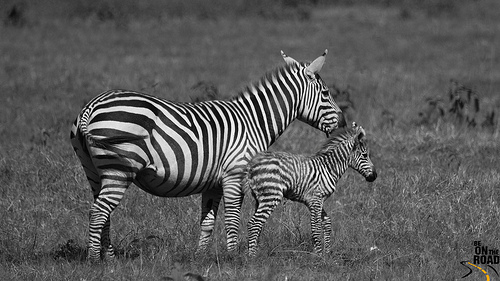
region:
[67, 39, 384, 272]
and adult and baby zebra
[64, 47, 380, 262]
baby zebra walks in front of an adult zebra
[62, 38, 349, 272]
black and white striped zebra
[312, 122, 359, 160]
fluffy black and white zebra mane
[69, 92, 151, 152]
black and white zebra tail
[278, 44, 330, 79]
ears on a zebra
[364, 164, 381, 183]
black nose of a baby zebra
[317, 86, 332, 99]
black eye of a zebra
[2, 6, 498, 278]
black and white image of zebras in a field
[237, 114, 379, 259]
fluffy fur on a baby zebra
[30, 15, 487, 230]
these are zebras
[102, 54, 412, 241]
there are two zebras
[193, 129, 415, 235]
this is a baby zebra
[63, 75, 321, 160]
this is the mother zebra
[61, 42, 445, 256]
the zebras are striped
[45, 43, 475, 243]
this is in black and white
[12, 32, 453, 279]
this is a monochromatic style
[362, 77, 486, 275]
the ground here is grass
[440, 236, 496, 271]
this photo is watermarked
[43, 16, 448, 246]
this is in the wild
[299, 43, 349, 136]
face of the zebra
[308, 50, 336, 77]
ear of the zebra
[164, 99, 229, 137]
black and white skin of zebra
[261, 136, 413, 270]
a small zebra on grass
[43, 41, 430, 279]
two zebras in grass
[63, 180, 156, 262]
legs of the zebra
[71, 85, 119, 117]
tail of the zebra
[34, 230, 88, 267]
shadow of the zebra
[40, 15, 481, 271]
beautiful view of grass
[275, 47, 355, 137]
Head of striped zebra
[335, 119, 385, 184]
Head of striped zebra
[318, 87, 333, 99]
Eye of striped zebra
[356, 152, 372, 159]
Eye of striped zebra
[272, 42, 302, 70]
Ear of striped zebra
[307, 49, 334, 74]
Ear of striped zebra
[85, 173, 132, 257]
Leg of striped zebra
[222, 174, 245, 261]
Leg of striped zebra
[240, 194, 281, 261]
Leg of striped zebra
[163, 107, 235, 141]
Part of zebra's back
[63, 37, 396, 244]
The zebras are walking.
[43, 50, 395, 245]
They are in the grass.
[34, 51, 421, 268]
The baby is next to the adult.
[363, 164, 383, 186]
His nose is black.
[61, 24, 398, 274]
The zebra is black and white.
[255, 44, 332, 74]
His ears are white.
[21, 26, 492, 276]
The grass is tall.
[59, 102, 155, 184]
The tail is wagging.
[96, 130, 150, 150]
The hair is black.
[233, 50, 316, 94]
His mane is short.